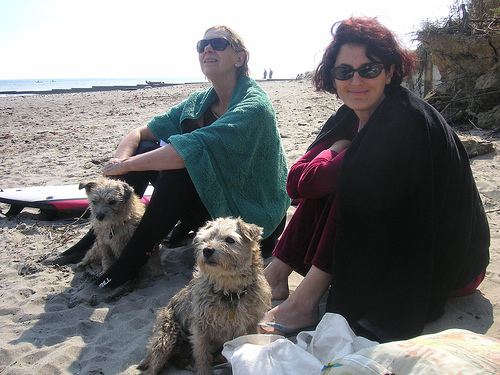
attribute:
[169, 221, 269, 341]
dog — white, tan, looking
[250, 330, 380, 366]
towel — white, green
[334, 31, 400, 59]
hair — short, burgundy, red, reddish, dark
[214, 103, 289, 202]
towel — green, dark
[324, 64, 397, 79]
shades — black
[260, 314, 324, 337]
flip flops — white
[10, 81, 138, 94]
water — blue, clear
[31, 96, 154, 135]
sand — brown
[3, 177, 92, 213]
surfboard — red, white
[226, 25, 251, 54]
hair — blonde, light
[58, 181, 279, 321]
dogs — tan, sitting, same, small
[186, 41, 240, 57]
sunglasses — black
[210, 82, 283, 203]
shawl — green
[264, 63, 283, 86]
people — walking, standing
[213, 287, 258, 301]
collar — black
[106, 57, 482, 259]
women — sitting, looking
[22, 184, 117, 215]
device — pink, white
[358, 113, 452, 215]
towel — black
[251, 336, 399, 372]
bag — white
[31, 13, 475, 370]
photo — daytime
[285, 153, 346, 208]
shirt — long